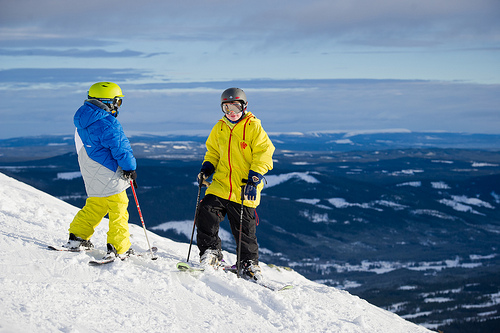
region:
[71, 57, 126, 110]
A person wearing a yellow helmet.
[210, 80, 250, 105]
A person wearing a silver helmet.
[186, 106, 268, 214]
A person wearing a yellow jacket.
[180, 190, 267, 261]
A person wearing black pants.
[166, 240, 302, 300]
Skis attached to a person's feet.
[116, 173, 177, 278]
A person holding a ski pole.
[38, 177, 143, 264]
A person wearing yellow pants.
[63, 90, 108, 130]
The hood on the jacket is blue.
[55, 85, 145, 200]
The jacket is blue, white, an gray.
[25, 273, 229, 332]
Snow on the ground.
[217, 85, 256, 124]
the head of a person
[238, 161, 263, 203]
the hand of a person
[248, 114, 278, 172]
the arm of a person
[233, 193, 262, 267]
the leg of a person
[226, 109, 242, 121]
the mouth of a person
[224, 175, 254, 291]
a black ski pole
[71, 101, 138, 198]
a blue and white coat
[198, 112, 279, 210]
a yellow coat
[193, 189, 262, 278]
a pair of black pants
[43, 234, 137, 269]
a pair of skis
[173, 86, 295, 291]
A boy in a yellow jacket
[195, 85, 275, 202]
The jacket has a red zipper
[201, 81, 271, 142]
The boy has a grey helmet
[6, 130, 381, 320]
The mountain is covered in snow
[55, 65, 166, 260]
The boy is wearing a blue and white jacket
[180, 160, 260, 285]
The boy has black ski poles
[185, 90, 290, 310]
The boy is wearing black pants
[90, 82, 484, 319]
The mountains are blue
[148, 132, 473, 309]
The mountains have patches of snow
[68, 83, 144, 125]
The boy is wearing goggles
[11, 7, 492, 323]
skiers on a mountain slope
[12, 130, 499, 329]
the valley below has patches of snow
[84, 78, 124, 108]
the person has a yellow helmet on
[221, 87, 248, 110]
the person has a black helmet on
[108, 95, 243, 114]
both skiers are wearing goggles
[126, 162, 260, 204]
both skiers have ski gloves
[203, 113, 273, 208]
a yellow down jacket is worn by the girl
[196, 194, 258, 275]
the girl is wearing black ski pants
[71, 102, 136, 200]
the boy is wearing a down jacket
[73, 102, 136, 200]
the jacket is white and blue with a hoodie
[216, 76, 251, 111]
red and gray helmet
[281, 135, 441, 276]
mountains with snow on them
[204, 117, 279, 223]
yellow and red jacket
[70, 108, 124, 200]
blue and white jacket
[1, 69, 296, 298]
two people on a mountain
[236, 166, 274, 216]
blue and yellow glove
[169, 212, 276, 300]
a pair of black ski pants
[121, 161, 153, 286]
red and silver ski pole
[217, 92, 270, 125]
goggles and helmet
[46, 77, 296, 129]
yellow and gray helmets